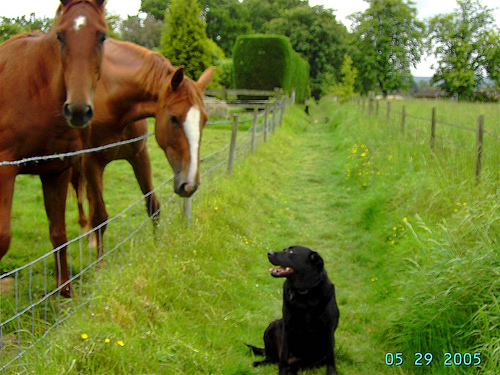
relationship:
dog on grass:
[245, 241, 339, 373] [0, 92, 499, 372]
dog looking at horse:
[245, 241, 339, 373] [4, 5, 102, 305]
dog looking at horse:
[245, 241, 339, 373] [68, 34, 215, 243]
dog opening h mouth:
[245, 241, 339, 373] [264, 256, 293, 281]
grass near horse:
[0, 92, 499, 372] [4, 5, 102, 305]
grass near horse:
[0, 92, 499, 372] [84, 31, 209, 272]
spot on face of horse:
[177, 98, 207, 192] [73, 20, 216, 276]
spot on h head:
[72, 13, 88, 27] [46, 5, 113, 128]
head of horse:
[46, 5, 113, 128] [4, 5, 102, 305]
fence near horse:
[1, 94, 304, 352] [4, 2, 113, 312]